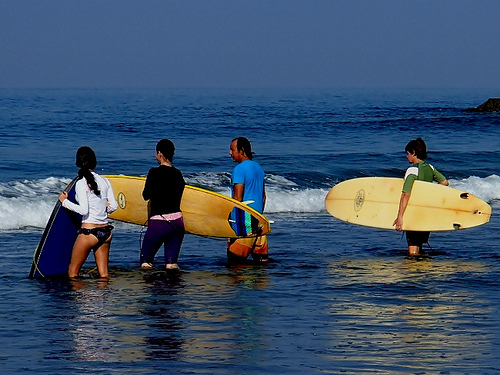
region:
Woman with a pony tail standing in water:
[57, 143, 130, 297]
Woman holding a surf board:
[37, 146, 157, 281]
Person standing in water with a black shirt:
[131, 138, 204, 275]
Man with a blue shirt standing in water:
[217, 131, 285, 257]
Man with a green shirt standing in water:
[333, 126, 495, 283]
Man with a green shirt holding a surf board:
[329, 132, 496, 268]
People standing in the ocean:
[58, 89, 465, 254]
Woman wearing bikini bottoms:
[48, 146, 155, 298]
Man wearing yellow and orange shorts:
[225, 135, 277, 272]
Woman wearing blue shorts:
[136, 135, 213, 286]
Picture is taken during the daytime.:
[10, 8, 499, 333]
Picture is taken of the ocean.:
[7, 58, 497, 311]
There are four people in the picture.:
[41, 101, 455, 272]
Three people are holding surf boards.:
[21, 125, 483, 304]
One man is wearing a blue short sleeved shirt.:
[226, 162, 275, 229]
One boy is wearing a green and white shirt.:
[382, 138, 458, 250]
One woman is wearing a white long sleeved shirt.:
[62, 172, 116, 228]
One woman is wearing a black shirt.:
[137, 164, 200, 218]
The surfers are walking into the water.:
[12, 158, 499, 296]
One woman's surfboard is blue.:
[29, 175, 109, 285]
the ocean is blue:
[4, 2, 498, 96]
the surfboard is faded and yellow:
[321, 174, 493, 238]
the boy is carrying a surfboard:
[324, 127, 493, 262]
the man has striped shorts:
[229, 237, 269, 267]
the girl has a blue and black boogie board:
[26, 170, 88, 283]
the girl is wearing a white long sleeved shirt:
[62, 171, 121, 225]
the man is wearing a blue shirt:
[228, 157, 270, 217]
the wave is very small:
[1, 172, 498, 230]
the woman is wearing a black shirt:
[138, 162, 189, 218]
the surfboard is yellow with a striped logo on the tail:
[98, 171, 272, 241]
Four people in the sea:
[41, 131, 495, 292]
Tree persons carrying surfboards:
[20, 128, 494, 303]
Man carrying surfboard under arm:
[320, 131, 496, 268]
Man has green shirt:
[320, 120, 495, 295]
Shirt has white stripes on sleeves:
[386, 160, 452, 195]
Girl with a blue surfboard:
[30, 136, 116, 291]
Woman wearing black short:
[128, 130, 196, 278]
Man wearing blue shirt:
[218, 128, 279, 282]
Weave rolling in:
[2, 170, 497, 235]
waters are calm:
[4, 224, 496, 372]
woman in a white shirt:
[65, 141, 120, 290]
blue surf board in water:
[29, 173, 92, 283]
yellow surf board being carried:
[95, 168, 272, 247]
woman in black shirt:
[138, 141, 192, 282]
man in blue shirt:
[229, 138, 269, 272]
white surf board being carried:
[320, 176, 498, 243]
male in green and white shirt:
[401, 137, 441, 266]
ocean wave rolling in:
[5, 168, 490, 224]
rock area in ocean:
[461, 76, 497, 128]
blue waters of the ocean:
[4, 79, 497, 170]